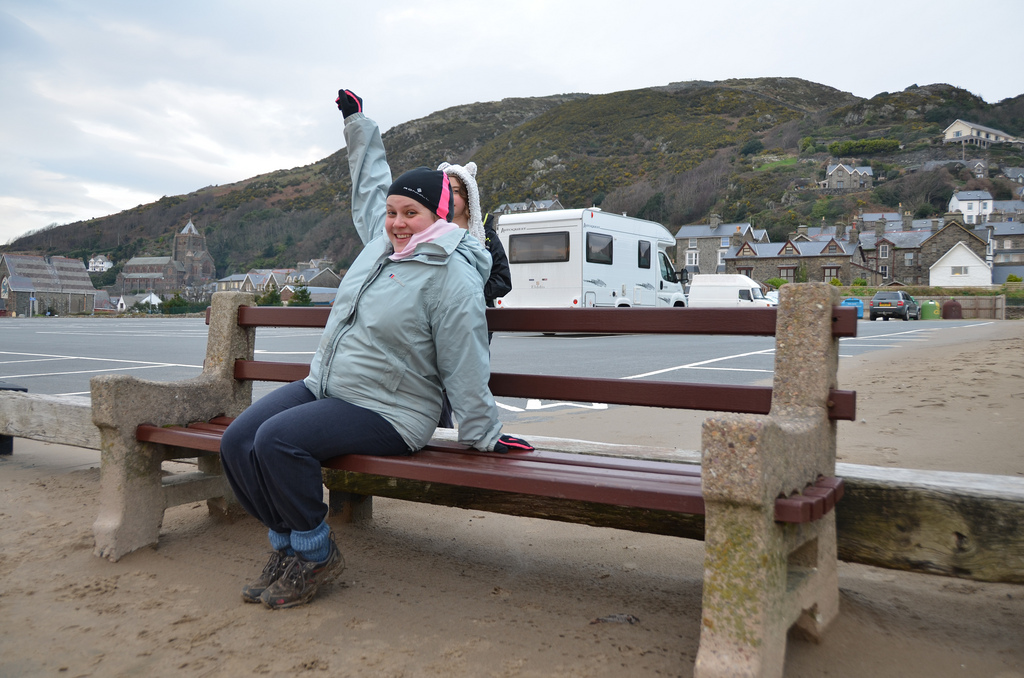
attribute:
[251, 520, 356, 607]
shoes — black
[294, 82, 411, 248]
arm — extended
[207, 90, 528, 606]
girl — sitting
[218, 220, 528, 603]
clothing — warm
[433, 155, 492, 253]
hat — white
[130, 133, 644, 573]
girl — sitting down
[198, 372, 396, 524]
pants — blue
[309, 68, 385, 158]
glove — black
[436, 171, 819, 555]
bench — wood, stone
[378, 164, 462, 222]
cap — pink, blue, beanie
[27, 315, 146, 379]
white line — drawn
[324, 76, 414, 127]
glove — red, black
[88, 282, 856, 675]
bench — brown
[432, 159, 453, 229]
stripe — pink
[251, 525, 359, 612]
shoes — dark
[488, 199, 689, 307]
trailer — white, mini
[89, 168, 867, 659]
woman/bench — sitting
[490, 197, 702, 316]
camper — white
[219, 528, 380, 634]
shoes — brown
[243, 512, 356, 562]
socks — blue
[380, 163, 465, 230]
hat — black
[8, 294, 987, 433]
lot — parking